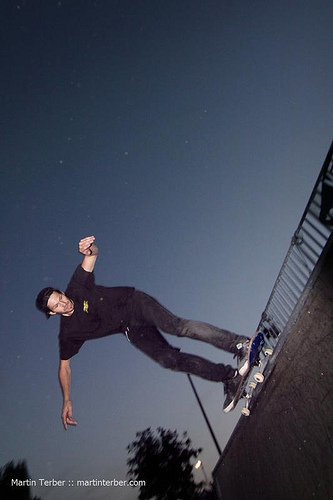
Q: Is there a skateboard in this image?
A: Yes, there is a skateboard.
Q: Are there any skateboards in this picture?
A: Yes, there is a skateboard.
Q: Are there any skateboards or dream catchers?
A: Yes, there is a skateboard.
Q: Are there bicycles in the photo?
A: No, there are no bicycles.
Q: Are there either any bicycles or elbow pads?
A: No, there are no bicycles or elbow pads.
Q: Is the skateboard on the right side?
A: Yes, the skateboard is on the right of the image.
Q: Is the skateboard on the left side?
A: No, the skateboard is on the right of the image.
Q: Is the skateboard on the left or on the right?
A: The skateboard is on the right of the image.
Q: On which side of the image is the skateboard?
A: The skateboard is on the right of the image.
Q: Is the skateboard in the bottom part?
A: Yes, the skateboard is in the bottom of the image.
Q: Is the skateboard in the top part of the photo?
A: No, the skateboard is in the bottom of the image.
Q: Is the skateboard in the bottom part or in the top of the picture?
A: The skateboard is in the bottom of the image.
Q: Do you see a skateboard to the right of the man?
A: Yes, there is a skateboard to the right of the man.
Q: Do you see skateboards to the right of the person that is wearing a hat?
A: Yes, there is a skateboard to the right of the man.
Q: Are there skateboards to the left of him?
A: No, the skateboard is to the right of the man.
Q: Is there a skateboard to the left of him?
A: No, the skateboard is to the right of the man.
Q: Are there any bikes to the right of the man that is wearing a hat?
A: No, there is a skateboard to the right of the man.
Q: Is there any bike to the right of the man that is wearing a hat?
A: No, there is a skateboard to the right of the man.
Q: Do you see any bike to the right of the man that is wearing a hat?
A: No, there is a skateboard to the right of the man.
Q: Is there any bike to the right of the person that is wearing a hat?
A: No, there is a skateboard to the right of the man.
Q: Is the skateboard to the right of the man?
A: Yes, the skateboard is to the right of the man.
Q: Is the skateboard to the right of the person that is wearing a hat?
A: Yes, the skateboard is to the right of the man.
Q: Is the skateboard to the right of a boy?
A: No, the skateboard is to the right of the man.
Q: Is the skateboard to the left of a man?
A: No, the skateboard is to the right of a man.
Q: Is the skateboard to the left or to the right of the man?
A: The skateboard is to the right of the man.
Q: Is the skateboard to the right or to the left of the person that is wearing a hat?
A: The skateboard is to the right of the man.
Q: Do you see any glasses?
A: No, there are no glasses.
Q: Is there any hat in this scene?
A: Yes, there is a hat.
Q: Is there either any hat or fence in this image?
A: Yes, there is a hat.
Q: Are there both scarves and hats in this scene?
A: No, there is a hat but no scarves.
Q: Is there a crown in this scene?
A: No, there are no crowns.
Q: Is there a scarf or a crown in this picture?
A: No, there are no crowns or scarves.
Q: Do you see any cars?
A: No, there are no cars.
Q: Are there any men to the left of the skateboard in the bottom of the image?
A: Yes, there is a man to the left of the skateboard.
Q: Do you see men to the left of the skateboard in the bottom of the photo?
A: Yes, there is a man to the left of the skateboard.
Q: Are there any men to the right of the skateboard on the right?
A: No, the man is to the left of the skateboard.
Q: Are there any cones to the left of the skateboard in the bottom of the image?
A: No, there is a man to the left of the skateboard.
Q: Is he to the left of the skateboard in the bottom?
A: Yes, the man is to the left of the skateboard.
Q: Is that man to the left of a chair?
A: No, the man is to the left of the skateboard.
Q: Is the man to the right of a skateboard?
A: No, the man is to the left of a skateboard.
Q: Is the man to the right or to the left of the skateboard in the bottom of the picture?
A: The man is to the left of the skateboard.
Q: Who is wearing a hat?
A: The man is wearing a hat.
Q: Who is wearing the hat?
A: The man is wearing a hat.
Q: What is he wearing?
A: The man is wearing a hat.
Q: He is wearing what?
A: The man is wearing a hat.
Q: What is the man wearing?
A: The man is wearing a hat.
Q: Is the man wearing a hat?
A: Yes, the man is wearing a hat.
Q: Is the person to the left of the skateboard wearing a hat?
A: Yes, the man is wearing a hat.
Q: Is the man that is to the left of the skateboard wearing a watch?
A: No, the man is wearing a hat.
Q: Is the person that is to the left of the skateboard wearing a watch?
A: No, the man is wearing a hat.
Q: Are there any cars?
A: No, there are no cars.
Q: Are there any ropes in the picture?
A: No, there are no ropes.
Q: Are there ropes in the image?
A: No, there are no ropes.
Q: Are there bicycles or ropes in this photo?
A: No, there are no ropes or bicycles.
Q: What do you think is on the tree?
A: The leaves are on the tree.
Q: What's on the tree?
A: The leaves are on the tree.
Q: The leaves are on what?
A: The leaves are on the tree.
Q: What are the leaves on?
A: The leaves are on the tree.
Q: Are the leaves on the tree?
A: Yes, the leaves are on the tree.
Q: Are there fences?
A: Yes, there is a fence.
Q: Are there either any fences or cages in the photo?
A: Yes, there is a fence.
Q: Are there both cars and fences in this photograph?
A: No, there is a fence but no cars.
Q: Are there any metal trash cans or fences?
A: Yes, there is a metal fence.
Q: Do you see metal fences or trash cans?
A: Yes, there is a metal fence.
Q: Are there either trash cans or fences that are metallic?
A: Yes, the fence is metallic.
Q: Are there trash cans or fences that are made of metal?
A: Yes, the fence is made of metal.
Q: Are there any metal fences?
A: Yes, there is a metal fence.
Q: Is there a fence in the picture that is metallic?
A: Yes, there is a fence that is metallic.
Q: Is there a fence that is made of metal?
A: Yes, there is a fence that is made of metal.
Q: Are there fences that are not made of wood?
A: Yes, there is a fence that is made of metal.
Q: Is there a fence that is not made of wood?
A: Yes, there is a fence that is made of metal.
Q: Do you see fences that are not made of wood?
A: Yes, there is a fence that is made of metal.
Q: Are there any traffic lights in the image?
A: No, there are no traffic lights.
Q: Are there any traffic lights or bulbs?
A: No, there are no traffic lights or bulbs.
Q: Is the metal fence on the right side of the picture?
A: Yes, the fence is on the right of the image.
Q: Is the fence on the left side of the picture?
A: No, the fence is on the right of the image.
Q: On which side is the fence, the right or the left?
A: The fence is on the right of the image.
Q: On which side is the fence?
A: The fence is on the right of the image.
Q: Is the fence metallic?
A: Yes, the fence is metallic.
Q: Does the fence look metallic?
A: Yes, the fence is metallic.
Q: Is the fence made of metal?
A: Yes, the fence is made of metal.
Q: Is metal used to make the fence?
A: Yes, the fence is made of metal.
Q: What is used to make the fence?
A: The fence is made of metal.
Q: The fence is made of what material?
A: The fence is made of metal.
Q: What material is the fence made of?
A: The fence is made of metal.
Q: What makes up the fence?
A: The fence is made of metal.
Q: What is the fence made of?
A: The fence is made of metal.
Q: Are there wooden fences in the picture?
A: No, there is a fence but it is metallic.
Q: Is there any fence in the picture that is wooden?
A: No, there is a fence but it is metallic.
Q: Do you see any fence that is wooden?
A: No, there is a fence but it is metallic.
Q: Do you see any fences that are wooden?
A: No, there is a fence but it is metallic.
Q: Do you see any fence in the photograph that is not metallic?
A: No, there is a fence but it is metallic.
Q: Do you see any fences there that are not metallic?
A: No, there is a fence but it is metallic.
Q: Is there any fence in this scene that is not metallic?
A: No, there is a fence but it is metallic.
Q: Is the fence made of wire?
A: No, the fence is made of metal.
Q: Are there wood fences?
A: No, there is a fence but it is made of metal.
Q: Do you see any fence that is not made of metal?
A: No, there is a fence but it is made of metal.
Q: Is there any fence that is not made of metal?
A: No, there is a fence but it is made of metal.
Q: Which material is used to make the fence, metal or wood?
A: The fence is made of metal.